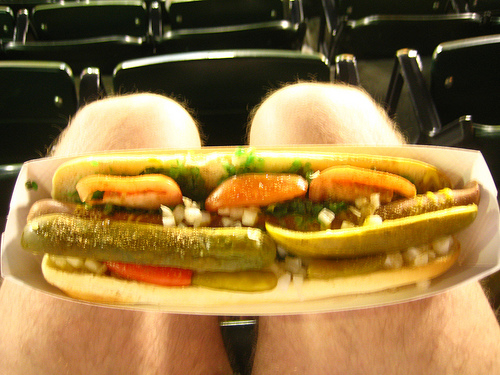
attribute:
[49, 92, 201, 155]
knee — hairy, pale, white, man's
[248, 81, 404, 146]
knee — hairy, pale, white, man's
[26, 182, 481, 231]
hotdog — delicious, footlong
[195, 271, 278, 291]
pepper — yellow, small, green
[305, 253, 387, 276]
pepper — yellow, small, green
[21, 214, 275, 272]
pickle — green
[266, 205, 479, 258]
pickle — green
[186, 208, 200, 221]
onion — white, chopped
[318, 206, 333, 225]
onion — white, chopped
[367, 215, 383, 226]
onion — white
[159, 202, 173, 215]
onion — white, chopped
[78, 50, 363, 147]
chair — black, green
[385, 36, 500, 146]
chair — black, green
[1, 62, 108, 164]
chair — black, green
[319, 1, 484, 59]
chair — black, green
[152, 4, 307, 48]
chair — black, green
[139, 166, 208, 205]
relish — green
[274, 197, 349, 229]
relish — green, plentiful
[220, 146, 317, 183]
relish — green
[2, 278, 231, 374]
leg — hairy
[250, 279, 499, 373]
leg — hairy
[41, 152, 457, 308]
hotdog bun — white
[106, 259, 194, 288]
pepper — red, grilled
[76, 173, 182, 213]
tomato — sliced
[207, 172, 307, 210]
tomato — sliced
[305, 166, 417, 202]
tomato — sliced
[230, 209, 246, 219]
onion — white, chopped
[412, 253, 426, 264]
onion — chopped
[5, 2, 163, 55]
chair — green, black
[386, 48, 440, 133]
armrest — shiny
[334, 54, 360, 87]
armrest — shiny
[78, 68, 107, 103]
armrest — shiny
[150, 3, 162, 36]
armrest — shiny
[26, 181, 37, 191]
relish — green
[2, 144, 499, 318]
box — white, paper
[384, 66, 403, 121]
leg — metal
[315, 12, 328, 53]
leg — metal